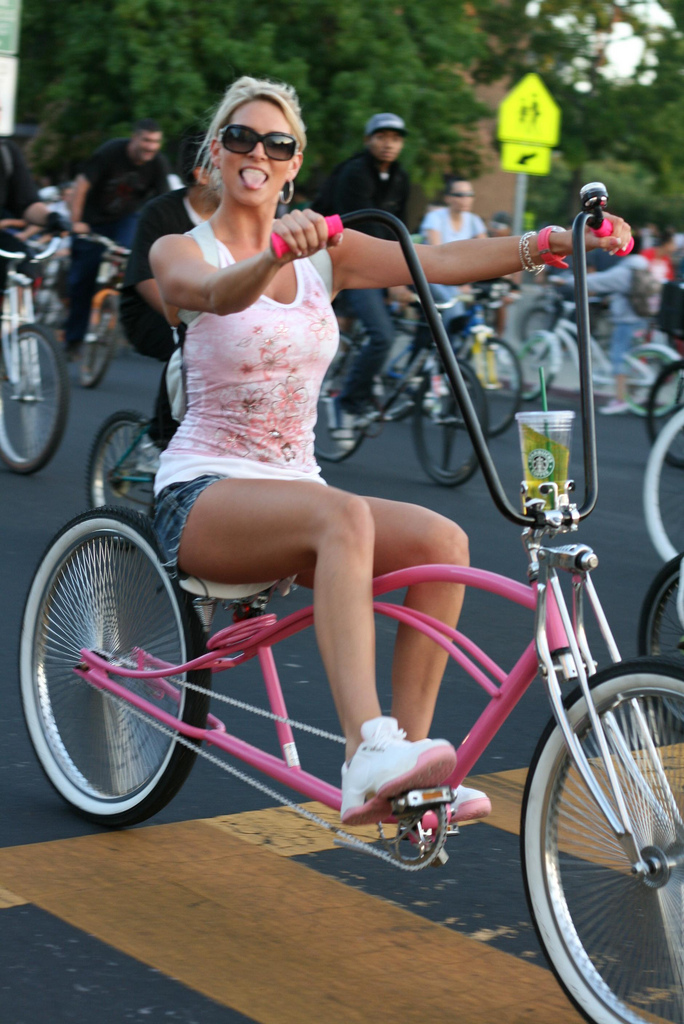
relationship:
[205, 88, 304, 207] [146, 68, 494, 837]
head of girl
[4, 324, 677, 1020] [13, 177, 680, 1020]
street under bike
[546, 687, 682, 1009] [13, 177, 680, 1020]
spokes on bike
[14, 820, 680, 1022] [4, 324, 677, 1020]
line on street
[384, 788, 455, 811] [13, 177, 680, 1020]
pedal of bike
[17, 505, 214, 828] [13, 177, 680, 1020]
tire of bike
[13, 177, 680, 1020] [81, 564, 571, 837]
bike with frame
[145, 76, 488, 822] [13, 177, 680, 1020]
woman riding bike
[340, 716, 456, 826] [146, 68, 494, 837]
shoes on girl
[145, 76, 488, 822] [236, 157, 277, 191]
woman sticking out tongue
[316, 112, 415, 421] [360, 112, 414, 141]
boy wearing hat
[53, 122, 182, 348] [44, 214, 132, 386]
man riding bike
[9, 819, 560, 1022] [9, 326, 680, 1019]
stripes painted on road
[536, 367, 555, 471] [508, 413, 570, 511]
straw in cup